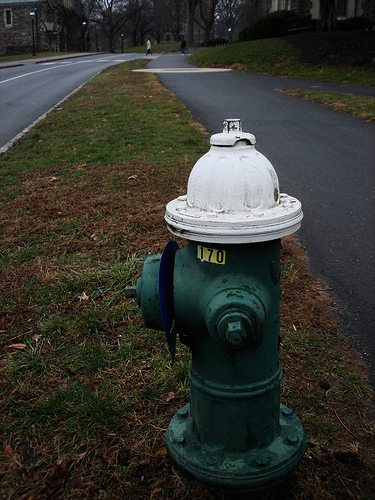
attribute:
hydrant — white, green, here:
[121, 114, 307, 493]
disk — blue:
[156, 239, 181, 362]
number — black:
[194, 242, 227, 269]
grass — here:
[2, 57, 373, 492]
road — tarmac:
[2, 49, 153, 156]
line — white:
[0, 50, 132, 85]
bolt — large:
[223, 319, 250, 348]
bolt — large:
[220, 114, 243, 137]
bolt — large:
[121, 280, 140, 303]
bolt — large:
[280, 401, 297, 420]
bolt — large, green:
[282, 430, 301, 446]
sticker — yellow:
[192, 241, 231, 270]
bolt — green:
[176, 405, 190, 419]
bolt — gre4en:
[169, 431, 187, 445]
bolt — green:
[202, 454, 223, 469]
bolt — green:
[252, 451, 271, 470]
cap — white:
[161, 112, 307, 248]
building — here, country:
[2, 1, 74, 59]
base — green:
[121, 239, 309, 490]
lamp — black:
[27, 8, 39, 59]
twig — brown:
[331, 403, 364, 444]